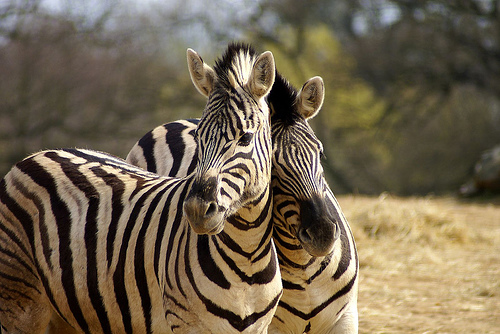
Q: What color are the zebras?
A: Black and white.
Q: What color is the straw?
A: Yellow.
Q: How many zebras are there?
A: Two.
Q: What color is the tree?
A: Green.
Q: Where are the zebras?
A: On the straw.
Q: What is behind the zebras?
A: Trees.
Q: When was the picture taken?
A: Daytime.